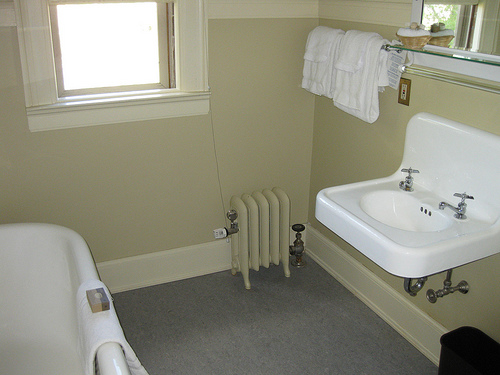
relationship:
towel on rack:
[297, 23, 392, 124] [362, 40, 498, 75]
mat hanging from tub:
[66, 277, 146, 374] [0, 220, 132, 374]